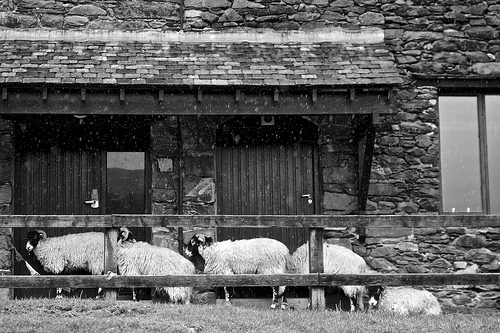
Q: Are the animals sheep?
A: Yes, all the animals are sheep.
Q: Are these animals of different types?
A: No, all the animals are sheep.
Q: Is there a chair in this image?
A: No, there are no chairs.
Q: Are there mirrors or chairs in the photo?
A: No, there are no chairs or mirrors.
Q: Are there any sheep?
A: Yes, there is a sheep.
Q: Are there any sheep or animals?
A: Yes, there is a sheep.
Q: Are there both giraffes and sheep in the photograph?
A: No, there is a sheep but no giraffes.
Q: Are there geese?
A: No, there are no geese.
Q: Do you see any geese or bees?
A: No, there are no geese or bees.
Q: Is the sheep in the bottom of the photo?
A: Yes, the sheep is in the bottom of the image.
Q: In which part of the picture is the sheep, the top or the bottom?
A: The sheep is in the bottom of the image.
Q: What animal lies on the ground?
A: The sheep lies on the ground.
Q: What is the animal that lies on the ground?
A: The animal is a sheep.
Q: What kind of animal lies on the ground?
A: The animal is a sheep.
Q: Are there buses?
A: No, there are no buses.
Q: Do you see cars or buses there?
A: No, there are no buses or cars.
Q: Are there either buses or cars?
A: No, there are no buses or cars.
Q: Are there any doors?
A: Yes, there is a door.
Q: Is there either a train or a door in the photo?
A: Yes, there is a door.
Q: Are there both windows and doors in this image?
A: Yes, there are both a door and a window.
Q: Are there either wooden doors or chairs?
A: Yes, there is a wood door.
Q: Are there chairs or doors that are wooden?
A: Yes, the door is wooden.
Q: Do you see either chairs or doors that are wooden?
A: Yes, the door is wooden.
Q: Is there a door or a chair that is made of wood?
A: Yes, the door is made of wood.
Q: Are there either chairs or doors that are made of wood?
A: Yes, the door is made of wood.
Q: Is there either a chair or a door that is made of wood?
A: Yes, the door is made of wood.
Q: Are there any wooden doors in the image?
A: Yes, there is a wood door.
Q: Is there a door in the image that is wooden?
A: Yes, there is a door that is wooden.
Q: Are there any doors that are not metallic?
A: Yes, there is a wooden door.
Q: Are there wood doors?
A: Yes, there is a door that is made of wood.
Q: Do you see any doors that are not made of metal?
A: Yes, there is a door that is made of wood.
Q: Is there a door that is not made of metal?
A: Yes, there is a door that is made of wood.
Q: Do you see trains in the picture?
A: No, there are no trains.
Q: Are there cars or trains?
A: No, there are no trains or cars.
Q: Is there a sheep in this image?
A: Yes, there is a sheep.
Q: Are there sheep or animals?
A: Yes, there is a sheep.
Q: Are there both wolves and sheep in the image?
A: No, there is a sheep but no wolves.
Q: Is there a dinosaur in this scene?
A: No, there are no dinosaurs.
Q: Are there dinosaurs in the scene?
A: No, there are no dinosaurs.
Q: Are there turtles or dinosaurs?
A: No, there are no dinosaurs or turtles.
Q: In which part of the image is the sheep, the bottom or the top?
A: The sheep is in the bottom of the image.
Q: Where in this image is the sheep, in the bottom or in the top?
A: The sheep is in the bottom of the image.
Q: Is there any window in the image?
A: Yes, there is a window.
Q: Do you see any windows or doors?
A: Yes, there is a window.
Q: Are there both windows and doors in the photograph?
A: Yes, there are both a window and a door.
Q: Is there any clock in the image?
A: No, there are no clocks.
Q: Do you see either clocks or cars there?
A: No, there are no clocks or cars.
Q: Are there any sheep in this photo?
A: Yes, there is a sheep.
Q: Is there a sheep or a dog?
A: Yes, there is a sheep.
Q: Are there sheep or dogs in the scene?
A: Yes, there is a sheep.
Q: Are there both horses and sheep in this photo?
A: No, there is a sheep but no horses.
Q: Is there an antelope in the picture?
A: No, there are no antelopes.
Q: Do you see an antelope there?
A: No, there are no antelopes.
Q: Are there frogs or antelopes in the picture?
A: No, there are no antelopes or frogs.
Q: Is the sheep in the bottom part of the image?
A: Yes, the sheep is in the bottom of the image.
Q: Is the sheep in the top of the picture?
A: No, the sheep is in the bottom of the image.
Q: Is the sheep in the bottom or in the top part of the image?
A: The sheep is in the bottom of the image.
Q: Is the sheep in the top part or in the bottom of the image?
A: The sheep is in the bottom of the image.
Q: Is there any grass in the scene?
A: Yes, there is grass.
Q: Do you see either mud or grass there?
A: Yes, there is grass.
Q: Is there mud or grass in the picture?
A: Yes, there is grass.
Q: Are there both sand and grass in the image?
A: No, there is grass but no sand.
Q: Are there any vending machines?
A: No, there are no vending machines.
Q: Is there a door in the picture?
A: Yes, there is a door.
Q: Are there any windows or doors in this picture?
A: Yes, there is a door.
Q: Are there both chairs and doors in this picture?
A: No, there is a door but no chairs.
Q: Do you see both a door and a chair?
A: No, there is a door but no chairs.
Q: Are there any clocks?
A: No, there are no clocks.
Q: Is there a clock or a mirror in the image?
A: No, there are no clocks or mirrors.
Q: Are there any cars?
A: No, there are no cars.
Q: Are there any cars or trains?
A: No, there are no cars or trains.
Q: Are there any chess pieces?
A: No, there are no chess pieces.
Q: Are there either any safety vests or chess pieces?
A: No, there are no chess pieces or safety vests.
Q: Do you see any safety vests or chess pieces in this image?
A: No, there are no chess pieces or safety vests.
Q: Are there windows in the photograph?
A: Yes, there is a window.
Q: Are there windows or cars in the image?
A: Yes, there is a window.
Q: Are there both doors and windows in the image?
A: Yes, there are both a window and doors.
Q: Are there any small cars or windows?
A: Yes, there is a small window.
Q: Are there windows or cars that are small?
A: Yes, the window is small.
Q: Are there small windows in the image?
A: Yes, there is a small window.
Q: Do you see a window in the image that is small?
A: Yes, there is a window that is small.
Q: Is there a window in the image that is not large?
A: Yes, there is a small window.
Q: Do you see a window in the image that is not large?
A: Yes, there is a small window.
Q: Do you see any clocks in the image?
A: No, there are no clocks.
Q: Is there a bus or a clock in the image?
A: No, there are no clocks or buses.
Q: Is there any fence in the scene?
A: Yes, there is a fence.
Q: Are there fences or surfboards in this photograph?
A: Yes, there is a fence.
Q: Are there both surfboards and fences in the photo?
A: No, there is a fence but no surfboards.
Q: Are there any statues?
A: No, there are no statues.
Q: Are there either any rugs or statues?
A: No, there are no statues or rugs.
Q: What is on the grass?
A: The fence is on the grass.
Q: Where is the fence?
A: The fence is on the grass.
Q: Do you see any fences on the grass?
A: Yes, there is a fence on the grass.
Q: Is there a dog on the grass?
A: No, there is a fence on the grass.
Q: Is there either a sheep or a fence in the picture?
A: Yes, there is a sheep.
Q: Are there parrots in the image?
A: No, there are no parrots.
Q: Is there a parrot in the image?
A: No, there are no parrots.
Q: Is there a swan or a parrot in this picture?
A: No, there are no parrots or swans.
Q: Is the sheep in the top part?
A: No, the sheep is in the bottom of the image.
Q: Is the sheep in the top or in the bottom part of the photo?
A: The sheep is in the bottom of the image.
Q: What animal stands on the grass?
A: The animal is a sheep.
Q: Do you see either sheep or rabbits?
A: Yes, there is a sheep.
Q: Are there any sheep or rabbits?
A: Yes, there is a sheep.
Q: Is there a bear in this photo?
A: No, there are no bears.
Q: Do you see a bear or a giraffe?
A: No, there are no bears or giraffes.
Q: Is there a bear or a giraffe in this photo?
A: No, there are no bears or giraffes.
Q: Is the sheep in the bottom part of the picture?
A: Yes, the sheep is in the bottom of the image.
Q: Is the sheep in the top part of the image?
A: No, the sheep is in the bottom of the image.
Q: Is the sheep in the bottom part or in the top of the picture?
A: The sheep is in the bottom of the image.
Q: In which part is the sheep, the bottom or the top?
A: The sheep is in the bottom of the image.